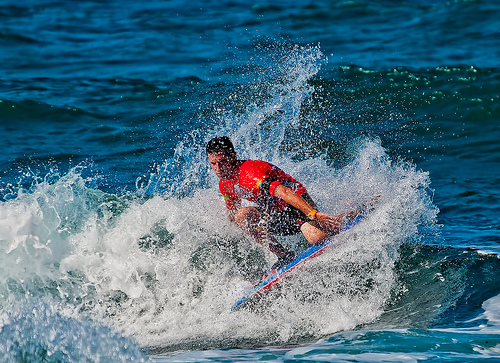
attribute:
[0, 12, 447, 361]
water — wave, in air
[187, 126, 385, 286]
man — kneeling down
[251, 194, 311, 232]
shorts — black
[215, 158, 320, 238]
wetsuit — red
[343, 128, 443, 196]
wave — small 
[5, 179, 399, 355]
wave — giant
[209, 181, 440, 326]
surfboard — blue and red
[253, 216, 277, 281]
thread — spiral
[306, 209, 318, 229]
watch — orange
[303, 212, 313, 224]
clock — surfer's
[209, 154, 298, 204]
shirt — red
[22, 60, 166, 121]
water ripples — water's, small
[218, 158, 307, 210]
shirt — red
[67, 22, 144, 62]
water — blue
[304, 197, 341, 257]
wristwatch — orange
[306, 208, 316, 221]
watch — yellow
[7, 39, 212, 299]
sea foam — white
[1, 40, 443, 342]
wave — large, white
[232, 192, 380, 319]
surfboard — blue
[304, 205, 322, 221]
clock — orange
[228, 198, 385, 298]
surfboard — blue, red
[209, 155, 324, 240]
wetsuit — red, black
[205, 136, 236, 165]
hair — short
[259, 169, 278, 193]
stripe — black